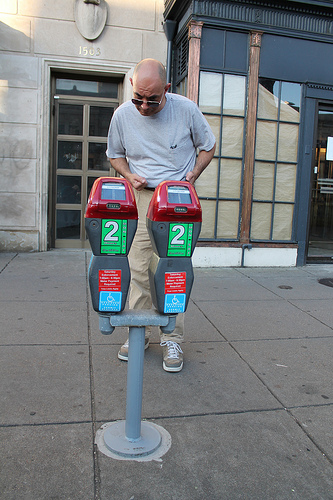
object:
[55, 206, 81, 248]
pane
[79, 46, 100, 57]
1503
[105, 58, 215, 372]
man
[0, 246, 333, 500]
ground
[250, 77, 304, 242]
windows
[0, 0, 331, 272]
building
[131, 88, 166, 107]
glasses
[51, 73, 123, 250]
door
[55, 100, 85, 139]
pane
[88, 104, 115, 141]
pane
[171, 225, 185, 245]
digit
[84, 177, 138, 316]
parking toll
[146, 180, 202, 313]
parking toll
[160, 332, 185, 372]
sneaker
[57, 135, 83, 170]
pane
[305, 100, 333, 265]
door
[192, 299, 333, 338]
tiles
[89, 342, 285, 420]
tiles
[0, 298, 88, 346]
tiles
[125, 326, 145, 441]
metal post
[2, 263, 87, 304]
cement square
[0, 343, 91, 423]
cement square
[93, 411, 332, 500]
cement square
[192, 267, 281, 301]
cement square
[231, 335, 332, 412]
cement square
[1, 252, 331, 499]
sidewalk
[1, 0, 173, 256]
wall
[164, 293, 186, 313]
sign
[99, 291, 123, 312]
sign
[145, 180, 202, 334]
meter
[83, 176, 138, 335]
meter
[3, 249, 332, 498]
pavement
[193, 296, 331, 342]
stone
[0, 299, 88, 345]
stone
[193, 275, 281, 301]
stone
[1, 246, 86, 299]
stone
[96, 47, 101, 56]
number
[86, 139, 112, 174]
pane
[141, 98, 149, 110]
nose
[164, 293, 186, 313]
handicapped label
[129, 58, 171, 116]
head